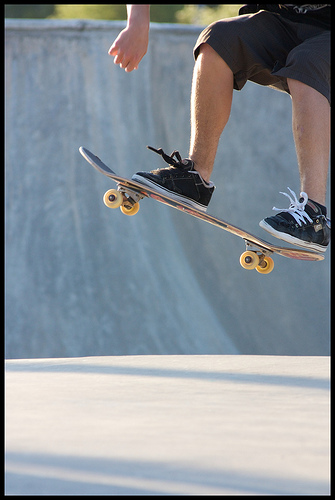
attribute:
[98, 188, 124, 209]
wheels — yellow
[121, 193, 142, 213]
wheels — yellow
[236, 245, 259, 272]
wheels — yellow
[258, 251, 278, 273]
wheels — yellow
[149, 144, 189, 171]
laces — black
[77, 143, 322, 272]
skateboard — concrete, park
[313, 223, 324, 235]
tag — red and white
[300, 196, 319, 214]
tag — red and white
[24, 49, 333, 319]
concrete barrier — gray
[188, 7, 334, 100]
shorts — black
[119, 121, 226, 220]
shoe — black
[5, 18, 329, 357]
wall — ramp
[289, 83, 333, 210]
leg — hairy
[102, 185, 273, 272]
wheels — white, plain, skateboard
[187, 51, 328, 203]
legs — bare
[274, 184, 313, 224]
lace — white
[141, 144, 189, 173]
shoe lace — black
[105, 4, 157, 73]
hand — person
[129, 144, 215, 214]
shoes — black, skate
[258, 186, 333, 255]
shoes — black, skate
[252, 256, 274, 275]
wheel — yellow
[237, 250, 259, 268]
wheel — yellow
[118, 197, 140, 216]
wheel — yellow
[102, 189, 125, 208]
wheel — yellow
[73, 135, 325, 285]
skateboard — black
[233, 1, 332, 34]
t-shirt — black, white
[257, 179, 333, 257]
shoe — black, tennis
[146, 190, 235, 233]
accents — red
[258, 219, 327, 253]
bottom — white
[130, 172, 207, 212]
bottom — white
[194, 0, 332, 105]
shorts — black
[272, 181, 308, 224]
lace — white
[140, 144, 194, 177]
lace — black